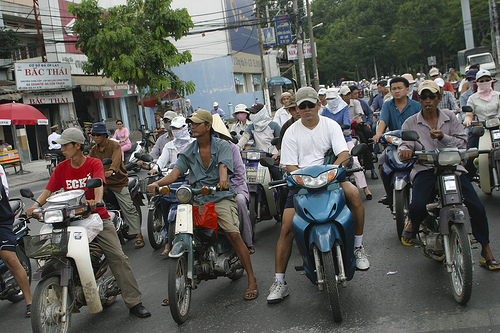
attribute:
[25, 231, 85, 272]
basket — black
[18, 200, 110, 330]
motorbike — white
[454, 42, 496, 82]
truck — white, tan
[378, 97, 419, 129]
shirt — dark blue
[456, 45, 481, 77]
back — black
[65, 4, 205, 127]
tree — green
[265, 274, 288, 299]
tennis shoe — white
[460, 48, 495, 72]
truck — white, black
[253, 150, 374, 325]
motorcycle — turquoise blue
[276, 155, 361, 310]
motorscooter — blue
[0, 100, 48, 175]
umbrella — red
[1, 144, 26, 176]
box — yellow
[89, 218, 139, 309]
pants — tan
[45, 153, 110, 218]
shirt — red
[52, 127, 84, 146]
cap — tan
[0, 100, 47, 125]
umbrella — red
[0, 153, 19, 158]
stripes — blue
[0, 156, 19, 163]
stripe — red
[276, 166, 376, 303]
motorbike — blue